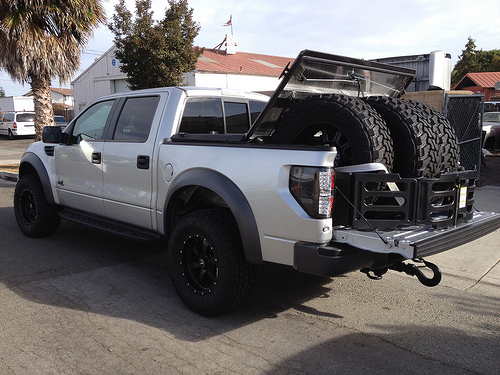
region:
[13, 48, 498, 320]
a silver pick up truck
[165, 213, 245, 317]
rear driver side tire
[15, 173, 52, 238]
front driver side tire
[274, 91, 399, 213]
oversized black tire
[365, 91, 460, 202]
oversized black tire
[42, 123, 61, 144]
truck driver's side rear view mirror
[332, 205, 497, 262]
a truck's open tailgate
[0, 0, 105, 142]
a palm tree in distance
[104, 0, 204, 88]
a green tree in distance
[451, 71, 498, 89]
a red roof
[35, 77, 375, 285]
silver and black truck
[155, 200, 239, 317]
jet black wheels on truck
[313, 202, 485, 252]
truck's tailgate is lowered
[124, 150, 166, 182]
black handles on doors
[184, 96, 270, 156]
black tinted rear windows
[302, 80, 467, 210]
large wheels on truck's bed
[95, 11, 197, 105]
green tree above truck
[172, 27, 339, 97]
red roof next to tree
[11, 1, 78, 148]
palm tree in front of truck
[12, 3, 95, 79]
brown leaves on palm tree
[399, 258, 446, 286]
towing hook on back of truck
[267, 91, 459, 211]
big tires in bed of truck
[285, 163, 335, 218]
tail lights of truck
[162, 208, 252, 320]
tire on back axle of truck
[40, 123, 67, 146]
rear view mirror on truck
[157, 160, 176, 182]
gas cap door on truck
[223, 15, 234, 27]
American flag flying on pole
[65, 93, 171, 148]
side windows in pickup truck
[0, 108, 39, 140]
white minivan parked in parking lot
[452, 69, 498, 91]
red roof of building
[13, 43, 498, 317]
a silver four door truck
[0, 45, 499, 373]
a four door truck parked on the side of the street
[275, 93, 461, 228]
three tires on the back of the truck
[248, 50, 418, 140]
a raised glass tinted cover on the back of the truck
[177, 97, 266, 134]
tinted windows on the back of the truck's cab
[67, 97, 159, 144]
two windows on the left side of the silver truck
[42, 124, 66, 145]
the left side view mirror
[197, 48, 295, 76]
a red roof on the top of the building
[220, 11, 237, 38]
a flag on top of the building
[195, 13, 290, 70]
a flag on top of the red roof on the building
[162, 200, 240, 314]
A wheel in the photo.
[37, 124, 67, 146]
A side mirror in the photo.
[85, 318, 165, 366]
A paved surface in the photo.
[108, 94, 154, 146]
Car window in the photo.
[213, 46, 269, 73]
Red roof in the photo.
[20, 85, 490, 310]
A truck in the photo.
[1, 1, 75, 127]
A tree in the photo.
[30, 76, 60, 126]
A tree trunk in the photo.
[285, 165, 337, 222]
Rear light on the car.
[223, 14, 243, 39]
A flag in the background.